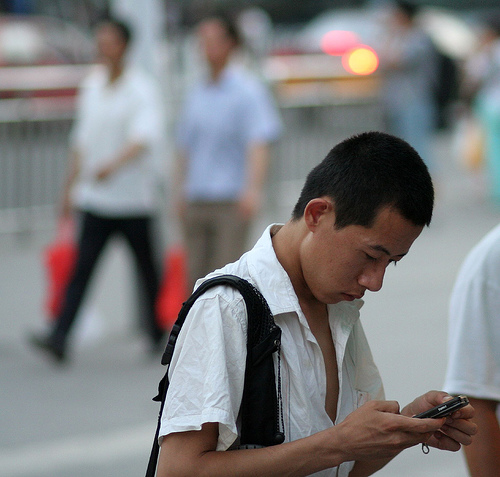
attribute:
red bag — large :
[42, 219, 79, 321]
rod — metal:
[315, 89, 362, 117]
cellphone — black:
[409, 390, 477, 425]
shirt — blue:
[176, 63, 294, 207]